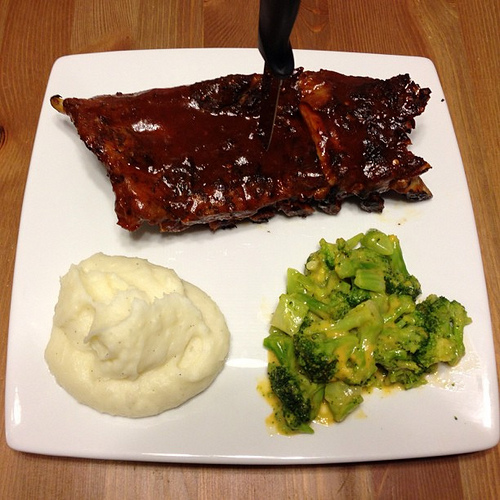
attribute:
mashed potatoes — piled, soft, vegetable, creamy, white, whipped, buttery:
[44, 252, 231, 420]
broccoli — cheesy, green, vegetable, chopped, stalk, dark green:
[354, 266, 386, 294]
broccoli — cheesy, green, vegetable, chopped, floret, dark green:
[293, 299, 382, 387]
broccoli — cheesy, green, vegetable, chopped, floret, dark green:
[414, 295, 472, 368]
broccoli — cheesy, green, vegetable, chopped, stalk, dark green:
[269, 294, 310, 338]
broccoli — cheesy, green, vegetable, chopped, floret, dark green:
[267, 366, 327, 431]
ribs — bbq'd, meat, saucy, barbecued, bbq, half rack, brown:
[50, 65, 432, 234]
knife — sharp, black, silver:
[259, 0, 302, 152]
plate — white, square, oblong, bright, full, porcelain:
[5, 46, 499, 468]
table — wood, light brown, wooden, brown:
[1, 0, 500, 499]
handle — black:
[258, 0, 301, 76]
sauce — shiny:
[65, 69, 367, 229]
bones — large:
[160, 178, 434, 233]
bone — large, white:
[49, 95, 66, 114]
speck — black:
[441, 97, 446, 102]